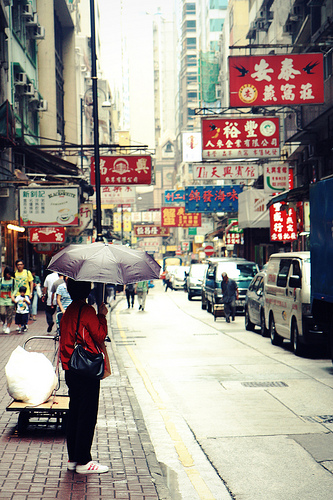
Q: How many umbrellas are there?
A: One.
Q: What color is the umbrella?
A: Grey.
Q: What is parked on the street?
A: Vehicles.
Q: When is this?
A: Daytime.